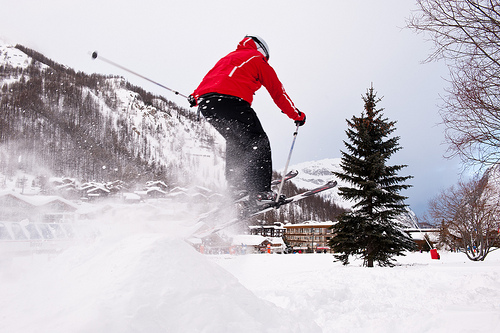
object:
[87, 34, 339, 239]
person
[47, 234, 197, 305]
snow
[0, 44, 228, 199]
mountain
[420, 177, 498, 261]
tree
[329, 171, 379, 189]
branch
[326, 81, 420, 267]
evegreen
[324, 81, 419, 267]
evergreen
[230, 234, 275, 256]
lodge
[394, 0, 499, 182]
trunks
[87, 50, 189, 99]
pole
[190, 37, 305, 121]
jacket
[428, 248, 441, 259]
object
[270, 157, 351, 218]
mountains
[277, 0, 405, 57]
skies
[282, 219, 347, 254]
bulidings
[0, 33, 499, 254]
background